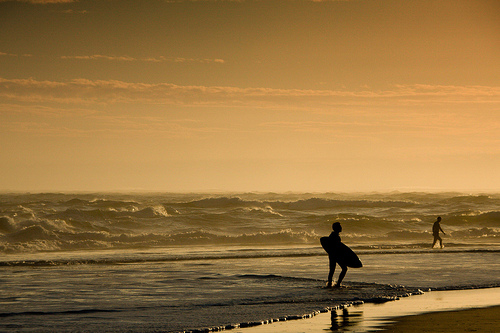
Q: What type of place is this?
A: It is a beach.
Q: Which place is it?
A: It is a beach.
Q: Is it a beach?
A: Yes, it is a beach.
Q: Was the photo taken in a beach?
A: Yes, it was taken in a beach.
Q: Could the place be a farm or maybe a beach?
A: It is a beach.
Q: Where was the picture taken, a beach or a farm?
A: It was taken at a beach.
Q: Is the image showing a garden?
A: No, the picture is showing a beach.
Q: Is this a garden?
A: No, it is a beach.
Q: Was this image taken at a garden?
A: No, the picture was taken in a beach.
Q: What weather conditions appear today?
A: It is cloudy.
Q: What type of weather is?
A: It is cloudy.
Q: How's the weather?
A: It is cloudy.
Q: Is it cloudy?
A: Yes, it is cloudy.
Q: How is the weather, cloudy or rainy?
A: It is cloudy.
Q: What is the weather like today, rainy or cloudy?
A: It is cloudy.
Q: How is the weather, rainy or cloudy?
A: It is cloudy.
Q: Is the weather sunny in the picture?
A: No, it is cloudy.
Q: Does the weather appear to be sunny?
A: No, it is cloudy.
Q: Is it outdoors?
A: Yes, it is outdoors.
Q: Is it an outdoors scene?
A: Yes, it is outdoors.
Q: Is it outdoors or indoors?
A: It is outdoors.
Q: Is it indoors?
A: No, it is outdoors.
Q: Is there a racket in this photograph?
A: No, there are no rackets.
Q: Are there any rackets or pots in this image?
A: No, there are no rackets or pots.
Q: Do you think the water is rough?
A: Yes, the water is rough.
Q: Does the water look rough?
A: Yes, the water is rough.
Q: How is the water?
A: The water is rough.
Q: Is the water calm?
A: No, the water is rough.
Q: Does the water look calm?
A: No, the water is rough.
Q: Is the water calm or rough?
A: The water is rough.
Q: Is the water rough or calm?
A: The water is rough.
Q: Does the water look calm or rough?
A: The water is rough.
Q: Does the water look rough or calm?
A: The water is rough.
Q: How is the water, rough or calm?
A: The water is rough.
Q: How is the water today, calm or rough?
A: The water is rough.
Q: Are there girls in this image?
A: No, there are no girls.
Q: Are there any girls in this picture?
A: No, there are no girls.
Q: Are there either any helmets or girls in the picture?
A: No, there are no girls or helmets.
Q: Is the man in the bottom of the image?
A: Yes, the man is in the bottom of the image.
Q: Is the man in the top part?
A: No, the man is in the bottom of the image.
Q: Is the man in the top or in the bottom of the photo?
A: The man is in the bottom of the image.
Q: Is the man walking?
A: Yes, the man is walking.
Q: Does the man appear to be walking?
A: Yes, the man is walking.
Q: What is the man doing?
A: The man is walking.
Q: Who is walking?
A: The man is walking.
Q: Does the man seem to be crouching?
A: No, the man is walking.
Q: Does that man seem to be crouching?
A: No, the man is walking.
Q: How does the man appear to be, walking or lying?
A: The man is walking.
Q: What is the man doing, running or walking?
A: The man is walking.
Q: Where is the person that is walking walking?
A: The man is walking on the beach.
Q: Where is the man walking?
A: The man is walking on the beach.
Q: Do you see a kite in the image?
A: No, there are no kites.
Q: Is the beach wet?
A: Yes, the beach is wet.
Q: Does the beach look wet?
A: Yes, the beach is wet.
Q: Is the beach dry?
A: No, the beach is wet.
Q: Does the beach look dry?
A: No, the beach is wet.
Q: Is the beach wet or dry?
A: The beach is wet.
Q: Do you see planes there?
A: No, there are no planes.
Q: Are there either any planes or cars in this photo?
A: No, there are no planes or cars.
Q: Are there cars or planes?
A: No, there are no planes or cars.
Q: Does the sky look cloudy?
A: Yes, the sky is cloudy.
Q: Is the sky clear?
A: No, the sky is cloudy.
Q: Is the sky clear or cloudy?
A: The sky is cloudy.